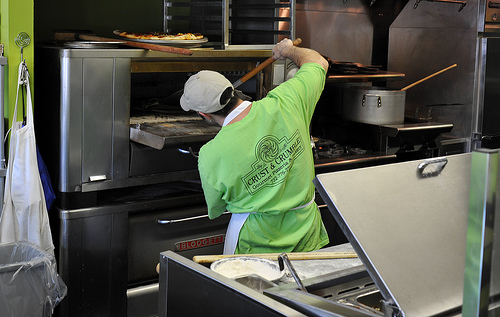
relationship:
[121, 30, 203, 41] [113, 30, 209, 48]
pizza in pan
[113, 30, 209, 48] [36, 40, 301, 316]
pan on top of oven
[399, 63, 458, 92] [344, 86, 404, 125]
spoon in pot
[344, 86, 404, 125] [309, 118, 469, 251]
pot on stove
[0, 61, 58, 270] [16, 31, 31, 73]
apron on hook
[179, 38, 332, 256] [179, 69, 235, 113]
man wearing baseball cap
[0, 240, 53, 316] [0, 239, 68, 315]
trash can has liner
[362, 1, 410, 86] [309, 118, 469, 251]
chimney vent from stove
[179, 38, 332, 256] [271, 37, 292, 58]
man has hand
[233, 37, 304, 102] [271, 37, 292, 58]
paddle in hand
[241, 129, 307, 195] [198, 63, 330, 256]
logo on shirt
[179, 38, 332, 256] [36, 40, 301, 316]
man in front of oven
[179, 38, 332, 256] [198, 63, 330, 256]
man in shirt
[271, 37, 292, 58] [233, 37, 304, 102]
hand on paddle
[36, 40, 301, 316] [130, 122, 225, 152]
oven has door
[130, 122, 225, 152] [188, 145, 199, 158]
door has handle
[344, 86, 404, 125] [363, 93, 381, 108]
pot has handle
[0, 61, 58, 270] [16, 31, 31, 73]
apron hanging on hook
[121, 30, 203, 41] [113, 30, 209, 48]
pizza on pan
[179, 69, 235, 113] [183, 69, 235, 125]
baseball cap on head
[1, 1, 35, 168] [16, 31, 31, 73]
wall has hook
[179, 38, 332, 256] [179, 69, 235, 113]
man in baseball cap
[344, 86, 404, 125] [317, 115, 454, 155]
pot on shelf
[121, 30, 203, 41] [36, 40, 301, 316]
pizza on top of oven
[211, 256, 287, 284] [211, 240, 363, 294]
flour on table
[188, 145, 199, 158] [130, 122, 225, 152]
handle on door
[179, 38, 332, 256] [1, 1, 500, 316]
man working in kitchen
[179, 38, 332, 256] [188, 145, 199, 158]
man holding handle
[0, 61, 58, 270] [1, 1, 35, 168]
apron hanging from wall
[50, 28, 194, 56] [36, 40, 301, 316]
paddle on top of oven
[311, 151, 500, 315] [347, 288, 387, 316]
lid above container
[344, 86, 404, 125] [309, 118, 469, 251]
pot on top of stove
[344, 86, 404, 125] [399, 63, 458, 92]
pot has spoon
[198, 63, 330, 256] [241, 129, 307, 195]
shirt has logo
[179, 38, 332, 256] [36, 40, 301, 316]
man looking into oven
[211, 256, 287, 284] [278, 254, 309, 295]
flour next to ladle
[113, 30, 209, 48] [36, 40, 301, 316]
pan on oven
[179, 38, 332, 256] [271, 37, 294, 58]
man wearing glove